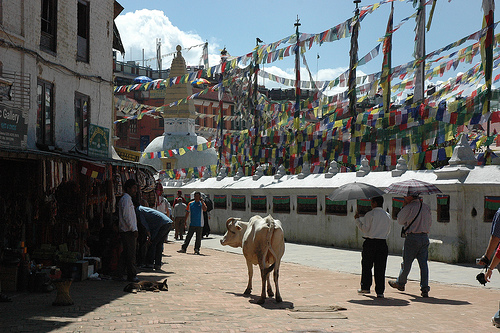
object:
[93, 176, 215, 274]
people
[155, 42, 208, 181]
statue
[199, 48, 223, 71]
background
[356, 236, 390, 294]
pants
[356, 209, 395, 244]
shirt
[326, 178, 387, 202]
umbrella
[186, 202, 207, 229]
shirt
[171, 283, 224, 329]
street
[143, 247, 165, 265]
jeans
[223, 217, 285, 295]
cow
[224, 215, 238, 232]
horn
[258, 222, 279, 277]
tail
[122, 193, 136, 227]
t-shirt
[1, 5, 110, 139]
building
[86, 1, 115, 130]
wall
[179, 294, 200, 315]
bricks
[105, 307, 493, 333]
ground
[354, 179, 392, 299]
man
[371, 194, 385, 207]
head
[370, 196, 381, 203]
hair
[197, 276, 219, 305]
middle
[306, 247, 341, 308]
road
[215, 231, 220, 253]
left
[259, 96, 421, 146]
flags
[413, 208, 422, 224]
strap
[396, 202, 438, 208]
shoulder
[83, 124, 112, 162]
sign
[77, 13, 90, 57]
window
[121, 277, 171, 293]
dog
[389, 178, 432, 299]
men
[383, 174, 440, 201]
umbrellas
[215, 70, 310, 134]
curtains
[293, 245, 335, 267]
pathway